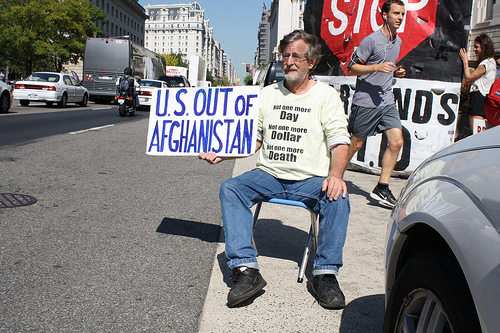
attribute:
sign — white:
[144, 86, 259, 157]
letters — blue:
[149, 90, 257, 154]